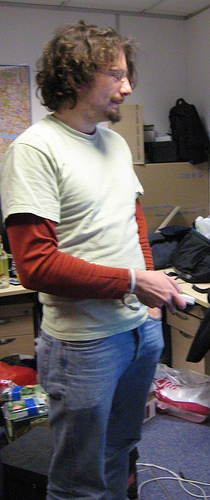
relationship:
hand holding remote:
[43, 250, 185, 318] [177, 292, 196, 306]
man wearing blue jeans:
[0, 16, 188, 500] [37, 315, 163, 498]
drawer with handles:
[0, 309, 36, 340] [0, 317, 15, 343]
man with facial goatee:
[0, 16, 188, 500] [102, 94, 124, 125]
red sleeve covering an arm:
[4, 213, 127, 299] [0, 144, 135, 298]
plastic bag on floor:
[149, 362, 209, 425] [130, 414, 207, 499]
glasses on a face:
[110, 68, 121, 82] [97, 45, 133, 119]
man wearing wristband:
[0, 16, 188, 500] [128, 265, 135, 293]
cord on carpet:
[135, 460, 204, 498] [0, 400, 210, 500]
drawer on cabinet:
[1, 314, 37, 335] [0, 293, 37, 361]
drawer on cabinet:
[1, 333, 37, 360] [0, 293, 37, 361]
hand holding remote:
[132, 263, 189, 321] [181, 294, 193, 306]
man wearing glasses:
[0, 16, 188, 500] [98, 67, 131, 82]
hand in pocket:
[147, 304, 161, 318] [147, 316, 165, 351]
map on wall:
[3, 58, 32, 115] [13, 10, 43, 33]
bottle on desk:
[0, 242, 11, 289] [0, 286, 36, 363]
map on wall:
[0, 64, 32, 167] [143, 63, 185, 93]